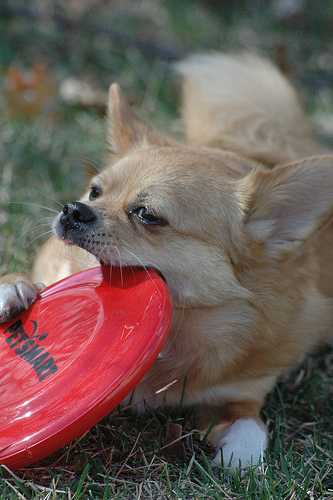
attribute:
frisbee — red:
[5, 251, 181, 462]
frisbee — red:
[1, 259, 170, 466]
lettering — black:
[7, 322, 56, 377]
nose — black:
[58, 201, 95, 228]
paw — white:
[211, 420, 268, 486]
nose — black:
[60, 201, 94, 242]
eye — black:
[132, 201, 167, 228]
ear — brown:
[242, 153, 332, 261]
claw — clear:
[12, 285, 33, 313]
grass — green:
[13, 46, 108, 157]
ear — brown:
[99, 77, 159, 158]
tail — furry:
[210, 63, 278, 141]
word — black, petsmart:
[3, 318, 67, 390]